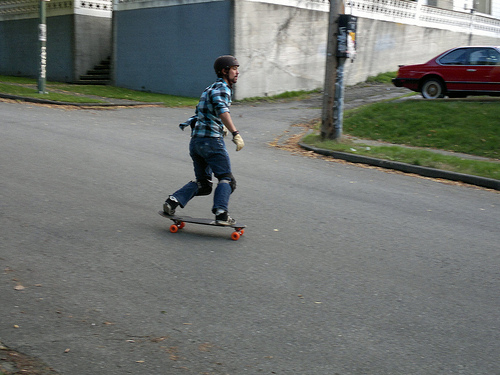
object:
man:
[161, 55, 246, 226]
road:
[1, 98, 500, 374]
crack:
[126, 333, 150, 340]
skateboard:
[156, 205, 246, 241]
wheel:
[230, 231, 241, 241]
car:
[390, 44, 500, 102]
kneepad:
[217, 171, 237, 193]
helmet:
[213, 53, 240, 85]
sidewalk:
[334, 125, 496, 178]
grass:
[1, 75, 204, 108]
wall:
[110, 1, 236, 101]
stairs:
[76, 76, 115, 84]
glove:
[231, 130, 245, 151]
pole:
[37, 0, 50, 94]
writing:
[40, 59, 47, 65]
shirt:
[178, 77, 233, 139]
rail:
[250, 1, 500, 42]